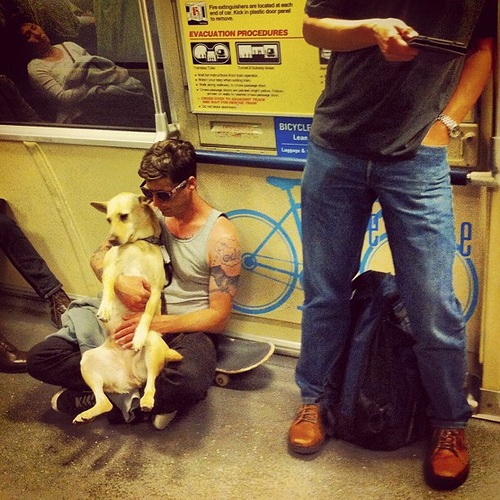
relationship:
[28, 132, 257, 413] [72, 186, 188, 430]
man sitting with dog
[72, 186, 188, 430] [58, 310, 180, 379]
dog on lap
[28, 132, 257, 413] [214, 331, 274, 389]
man sitting on skateboard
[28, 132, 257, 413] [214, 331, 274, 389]
man on skateboard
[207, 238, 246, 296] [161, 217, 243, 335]
tattoo on arm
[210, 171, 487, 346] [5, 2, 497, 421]
bicycle on wall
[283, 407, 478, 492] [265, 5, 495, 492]
boots on man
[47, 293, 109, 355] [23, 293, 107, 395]
coat on leg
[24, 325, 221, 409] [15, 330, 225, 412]
jeans on legs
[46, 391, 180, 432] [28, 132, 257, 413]
shoes on man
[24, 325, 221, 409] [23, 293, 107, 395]
jeans on leg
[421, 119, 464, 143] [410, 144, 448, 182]
hand in pocket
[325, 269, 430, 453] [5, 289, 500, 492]
backpack on ground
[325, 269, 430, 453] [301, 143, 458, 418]
backpack between legs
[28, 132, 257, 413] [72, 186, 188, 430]
man holding dog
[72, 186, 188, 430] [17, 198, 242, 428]
dog next to body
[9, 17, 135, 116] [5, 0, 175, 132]
reflection in window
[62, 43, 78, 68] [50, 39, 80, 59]
strap across shoulder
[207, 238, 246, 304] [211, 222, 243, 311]
tattoo on upper arm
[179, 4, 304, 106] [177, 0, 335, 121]
instructions on board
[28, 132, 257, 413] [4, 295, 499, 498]
man on floor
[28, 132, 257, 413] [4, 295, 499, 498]
man sitting on floor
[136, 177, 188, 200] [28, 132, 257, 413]
sunglasses on man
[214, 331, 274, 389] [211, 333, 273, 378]
skateboard used as seat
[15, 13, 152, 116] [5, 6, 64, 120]
woman in seat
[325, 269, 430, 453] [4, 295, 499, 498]
backpack on floor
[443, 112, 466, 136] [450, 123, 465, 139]
wristwatch with face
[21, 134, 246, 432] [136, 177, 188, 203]
guy has sunglasses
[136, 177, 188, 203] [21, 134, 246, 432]
sunglasses on guy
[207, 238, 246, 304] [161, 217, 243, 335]
tattoo on arm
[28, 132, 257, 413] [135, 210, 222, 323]
man wearing vest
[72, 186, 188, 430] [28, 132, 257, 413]
dog held by man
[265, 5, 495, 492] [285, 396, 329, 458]
man has boots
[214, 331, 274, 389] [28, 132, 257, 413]
skateboard under man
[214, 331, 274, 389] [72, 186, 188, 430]
skateboard under dog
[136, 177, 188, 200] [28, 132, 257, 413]
sunglasses worn by man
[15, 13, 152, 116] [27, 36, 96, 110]
woman in shirt